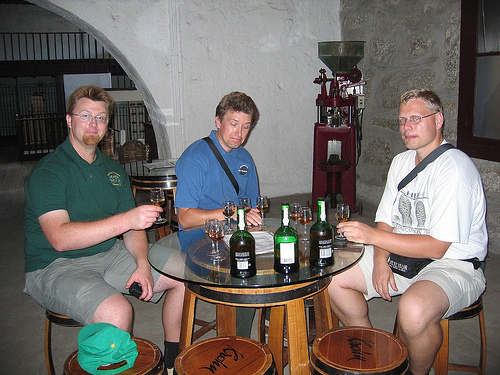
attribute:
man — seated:
[21, 84, 181, 358]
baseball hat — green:
[76, 322, 138, 374]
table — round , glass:
[148, 214, 367, 374]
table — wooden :
[149, 193, 369, 306]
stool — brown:
[297, 314, 411, 374]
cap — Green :
[72, 320, 134, 373]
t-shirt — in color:
[14, 135, 141, 278]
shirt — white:
[387, 177, 455, 247]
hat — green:
[64, 315, 141, 366]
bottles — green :
[226, 203, 338, 280]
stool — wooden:
[432, 297, 487, 373]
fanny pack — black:
[384, 252, 437, 277]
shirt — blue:
[164, 140, 263, 249]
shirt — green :
[21, 135, 138, 273]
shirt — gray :
[374, 140, 487, 265]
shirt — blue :
[173, 128, 260, 254]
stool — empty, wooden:
[172, 335, 277, 372]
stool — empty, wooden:
[307, 326, 410, 373]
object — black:
[124, 274, 152, 301]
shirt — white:
[357, 138, 484, 295]